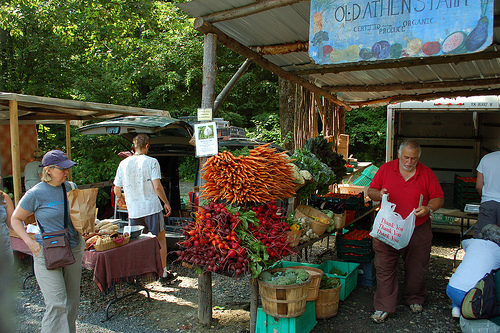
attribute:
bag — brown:
[35, 179, 76, 269]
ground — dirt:
[156, 285, 185, 332]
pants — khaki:
[29, 236, 91, 331]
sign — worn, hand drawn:
[306, 0, 497, 67]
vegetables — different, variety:
[200, 153, 309, 294]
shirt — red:
[371, 155, 440, 225]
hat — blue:
[39, 147, 77, 169]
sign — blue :
[297, 0, 494, 64]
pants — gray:
[36, 246, 88, 329]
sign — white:
[196, 105, 210, 155]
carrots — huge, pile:
[198, 139, 303, 203]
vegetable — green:
[261, 265, 308, 290]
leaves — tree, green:
[3, 3, 22, 38]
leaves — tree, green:
[30, 4, 51, 34]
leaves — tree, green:
[7, 57, 33, 90]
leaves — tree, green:
[82, 1, 110, 22]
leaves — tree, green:
[150, 46, 172, 75]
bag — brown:
[66, 186, 98, 231]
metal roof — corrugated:
[225, 11, 297, 49]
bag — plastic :
[371, 192, 418, 252]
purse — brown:
[36, 224, 76, 269]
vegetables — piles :
[179, 131, 354, 294]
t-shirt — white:
[112, 151, 161, 221]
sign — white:
[187, 110, 224, 165]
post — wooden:
[197, 31, 217, 324]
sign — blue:
[304, 0, 493, 73]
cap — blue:
[34, 144, 90, 170]